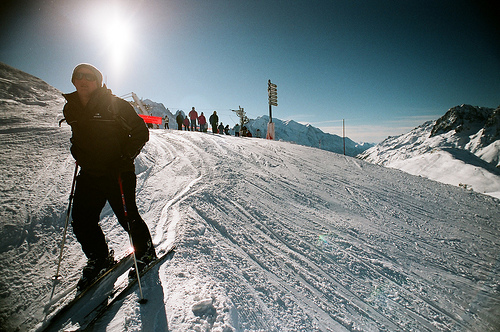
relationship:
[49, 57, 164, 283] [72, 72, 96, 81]
man wearing goggles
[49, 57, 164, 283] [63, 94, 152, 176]
man has coat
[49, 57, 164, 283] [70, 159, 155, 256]
man has pants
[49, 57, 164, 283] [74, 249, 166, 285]
man has shoes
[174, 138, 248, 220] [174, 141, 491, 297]
tracks are in snow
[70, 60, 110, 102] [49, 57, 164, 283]
head of man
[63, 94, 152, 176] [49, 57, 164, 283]
coat of man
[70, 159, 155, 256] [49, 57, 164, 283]
pants of man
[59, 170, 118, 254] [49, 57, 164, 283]
right leg of a man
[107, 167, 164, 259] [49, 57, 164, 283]
left leg of a man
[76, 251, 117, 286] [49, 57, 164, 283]
right foot of a man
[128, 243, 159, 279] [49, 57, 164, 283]
left foot of a man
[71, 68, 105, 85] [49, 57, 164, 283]
goggles of a man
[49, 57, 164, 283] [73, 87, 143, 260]
man wearing snow clothes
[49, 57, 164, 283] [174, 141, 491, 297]
man on snow